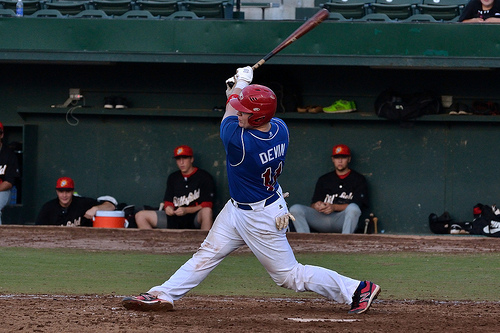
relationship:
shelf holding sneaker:
[15, 105, 497, 120] [323, 99, 354, 114]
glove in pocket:
[276, 211, 296, 234] [274, 210, 292, 235]